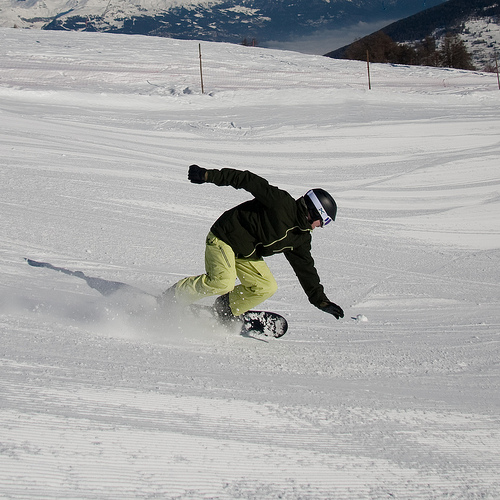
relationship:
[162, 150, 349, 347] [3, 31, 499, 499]
man riding slope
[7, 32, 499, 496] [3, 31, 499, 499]
snow covered slope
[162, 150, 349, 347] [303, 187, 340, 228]
man wearing helmet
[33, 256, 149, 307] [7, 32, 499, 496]
shadow on snow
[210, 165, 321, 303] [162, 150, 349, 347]
jacket on man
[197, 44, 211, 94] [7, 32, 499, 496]
pole sticking in snow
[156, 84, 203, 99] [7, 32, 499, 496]
pile of snow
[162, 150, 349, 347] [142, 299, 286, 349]
man on snowboard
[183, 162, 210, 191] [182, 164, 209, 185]
glove on hand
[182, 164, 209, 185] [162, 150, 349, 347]
hand of man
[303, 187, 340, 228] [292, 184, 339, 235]
helmet on head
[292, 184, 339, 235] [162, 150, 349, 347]
head of man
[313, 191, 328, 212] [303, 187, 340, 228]
stripe on helmet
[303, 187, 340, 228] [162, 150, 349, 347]
helmet of man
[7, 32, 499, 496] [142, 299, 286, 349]
snow on snowboard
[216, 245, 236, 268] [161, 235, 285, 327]
zipper on pants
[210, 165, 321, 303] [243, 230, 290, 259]
coat with stripe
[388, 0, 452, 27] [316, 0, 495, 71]
ridge on mountain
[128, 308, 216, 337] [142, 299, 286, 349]
snow from snowboard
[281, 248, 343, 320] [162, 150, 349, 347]
arm of man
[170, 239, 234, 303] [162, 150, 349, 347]
leg of man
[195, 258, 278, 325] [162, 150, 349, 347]
leg of man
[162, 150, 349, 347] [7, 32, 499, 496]
man in snow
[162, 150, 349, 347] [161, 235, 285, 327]
man wearing pants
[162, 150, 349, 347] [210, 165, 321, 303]
man wearing shirt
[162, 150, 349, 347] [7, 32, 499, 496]
man on snow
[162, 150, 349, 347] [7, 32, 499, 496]
man sliding on snow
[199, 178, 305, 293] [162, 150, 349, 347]
body of man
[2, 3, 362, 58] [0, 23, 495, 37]
mountains on horizon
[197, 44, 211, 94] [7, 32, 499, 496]
pole in snow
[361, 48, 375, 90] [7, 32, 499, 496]
pole in snow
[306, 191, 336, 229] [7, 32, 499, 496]
goggles of snow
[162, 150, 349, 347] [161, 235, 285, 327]
snowboarder wearing pants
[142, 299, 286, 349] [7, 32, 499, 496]
snowboard covered in snow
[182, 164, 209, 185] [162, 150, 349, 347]
hand of snowboarder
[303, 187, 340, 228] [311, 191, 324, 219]
helmet with band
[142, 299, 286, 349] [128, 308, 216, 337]
snowboard with snow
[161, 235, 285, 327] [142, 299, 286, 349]
pants for snowboard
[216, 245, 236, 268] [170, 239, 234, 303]
zipper on leg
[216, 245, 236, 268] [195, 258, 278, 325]
zipper on leg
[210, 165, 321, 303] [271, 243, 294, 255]
jacket with zipper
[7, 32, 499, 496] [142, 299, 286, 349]
snow under snowboard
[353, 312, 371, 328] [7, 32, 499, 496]
ball of snow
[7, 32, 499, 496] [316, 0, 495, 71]
snow covered mountain